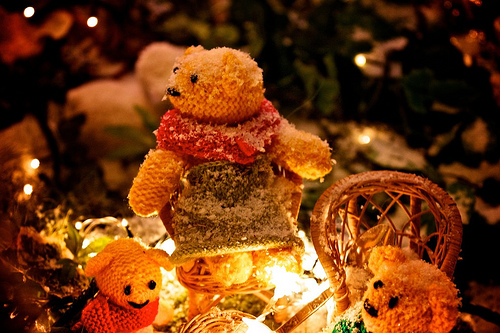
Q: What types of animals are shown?
A: Bears.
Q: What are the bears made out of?
A: Fabric and yarn.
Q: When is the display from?
A: Christmas.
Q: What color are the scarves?
A: Red.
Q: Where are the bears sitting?
A: In chairs.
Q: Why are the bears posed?
A: For decoration.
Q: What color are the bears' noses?
A: Black.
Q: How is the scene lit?
A: With artificial lights.